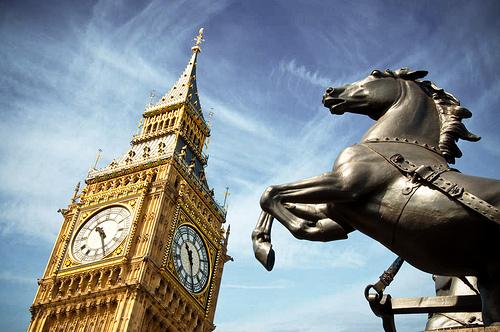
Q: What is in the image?
A: Horses.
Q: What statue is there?
A: Horse.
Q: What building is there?
A: Clocktower.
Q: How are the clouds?
A: Wispy.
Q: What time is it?
A: 10:25 AM.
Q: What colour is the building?
A: Golden.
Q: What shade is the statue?
A: Charcoal.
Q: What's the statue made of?
A: Metal.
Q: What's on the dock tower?
A: Clocks.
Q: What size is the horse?
A: Large.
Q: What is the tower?
A: Clock tower.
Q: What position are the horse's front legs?
A: Lifted.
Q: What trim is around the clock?
A: Gold.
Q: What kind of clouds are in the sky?
A: Wispy.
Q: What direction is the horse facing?
A: Left.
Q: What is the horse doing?
A: Rearing.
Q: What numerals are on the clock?
A: Roman.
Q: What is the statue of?
A: A horse.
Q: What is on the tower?
A: Clocks.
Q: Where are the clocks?
A: In the tower.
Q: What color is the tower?
A: Gold and grey.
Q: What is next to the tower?
A: A statue.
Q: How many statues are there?
A: One.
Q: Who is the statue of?
A: A horse.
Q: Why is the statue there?
A: To decorate the place.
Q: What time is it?
A: 10:27.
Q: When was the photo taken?
A: During the day.